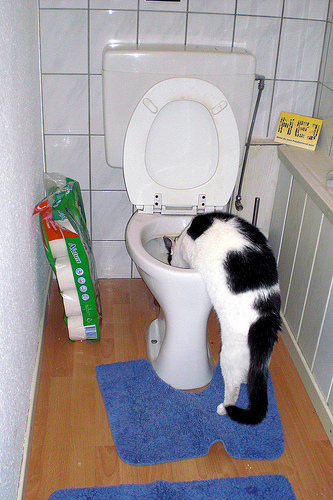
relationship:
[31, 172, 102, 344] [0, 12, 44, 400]
pack near wall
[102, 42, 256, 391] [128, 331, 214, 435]
toilet connected to floor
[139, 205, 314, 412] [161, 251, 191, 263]
cat with face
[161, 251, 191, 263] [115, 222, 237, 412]
face in toilet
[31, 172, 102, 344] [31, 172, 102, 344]
pack of pack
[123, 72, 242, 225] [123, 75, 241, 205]
lid of lid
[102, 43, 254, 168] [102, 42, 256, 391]
tank of toilet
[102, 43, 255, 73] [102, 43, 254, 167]
lid of toilet tank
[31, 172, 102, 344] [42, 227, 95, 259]
pack of rolls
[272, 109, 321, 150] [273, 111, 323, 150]
card with card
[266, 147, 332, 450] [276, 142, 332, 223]
wall boards with shelf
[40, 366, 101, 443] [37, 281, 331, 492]
design on floor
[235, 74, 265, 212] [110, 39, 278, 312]
metal pipe attached to toilet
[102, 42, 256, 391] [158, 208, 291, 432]
toilet with cat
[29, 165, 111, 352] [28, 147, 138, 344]
pack of toilet paper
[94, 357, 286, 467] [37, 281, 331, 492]
blue rug on floor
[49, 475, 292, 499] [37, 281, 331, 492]
mat on floor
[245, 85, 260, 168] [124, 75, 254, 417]
metal pipe on side of toilet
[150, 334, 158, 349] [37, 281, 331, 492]
screw on floor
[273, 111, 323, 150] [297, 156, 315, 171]
card on ledge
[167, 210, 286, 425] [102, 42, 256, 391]
cat crawling into toilet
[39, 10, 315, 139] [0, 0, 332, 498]
tiles in bathroom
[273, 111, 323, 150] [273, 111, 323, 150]
card on card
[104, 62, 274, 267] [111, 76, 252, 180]
toilet with lifted lid